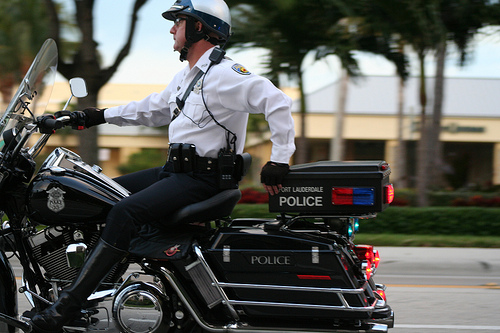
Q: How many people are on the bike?
A: One.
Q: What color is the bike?
A: Black.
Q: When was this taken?
A: During the day.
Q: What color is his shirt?
A: White.